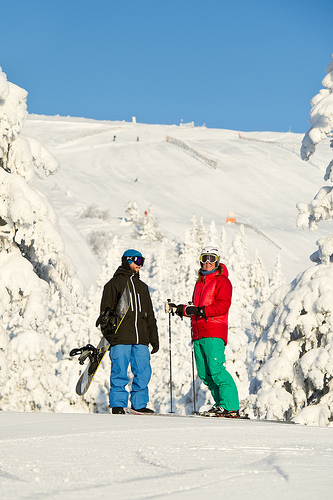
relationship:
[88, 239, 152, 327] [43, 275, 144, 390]
man with snowboard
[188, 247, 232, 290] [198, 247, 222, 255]
woman wearing helmet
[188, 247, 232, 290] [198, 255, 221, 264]
woman wearing goggles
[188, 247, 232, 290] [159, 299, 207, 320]
woman wearing gloves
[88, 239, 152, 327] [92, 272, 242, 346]
man wearing jacket